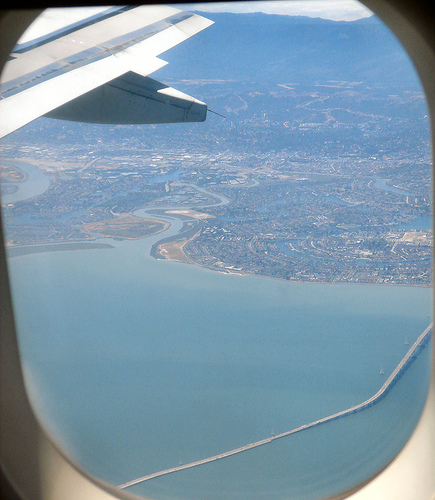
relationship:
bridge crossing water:
[101, 294, 433, 484] [1, 98, 431, 496]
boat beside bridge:
[403, 337, 408, 346] [112, 318, 430, 489]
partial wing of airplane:
[156, 410, 383, 436] [4, 8, 227, 147]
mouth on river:
[104, 228, 168, 251] [8, 243, 418, 498]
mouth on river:
[104, 228, 168, 251] [1, 157, 51, 208]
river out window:
[108, 166, 237, 250] [5, 12, 432, 498]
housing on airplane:
[40, 71, 207, 123] [3, 6, 433, 495]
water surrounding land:
[0, 160, 435, 500] [0, 12, 435, 287]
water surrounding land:
[0, 161, 52, 210] [0, 12, 435, 287]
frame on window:
[3, 367, 116, 478] [5, 12, 432, 498]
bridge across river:
[110, 322, 435, 492] [15, 227, 433, 487]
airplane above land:
[3, 6, 433, 495] [0, 12, 435, 287]